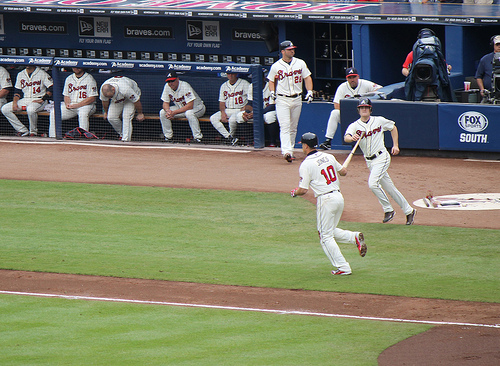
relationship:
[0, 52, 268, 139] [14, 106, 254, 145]
baseball players sitting on bench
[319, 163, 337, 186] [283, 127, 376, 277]
number on player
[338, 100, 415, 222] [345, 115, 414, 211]
baseball player wearing uniform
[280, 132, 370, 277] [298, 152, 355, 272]
baseball player wearing uniform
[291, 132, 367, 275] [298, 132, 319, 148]
baseball player wearing baseball helmet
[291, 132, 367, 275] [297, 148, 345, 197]
baseball player wearing shirt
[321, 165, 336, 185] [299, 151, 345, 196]
number on shirt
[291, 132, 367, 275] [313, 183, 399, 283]
baseball player wearing pants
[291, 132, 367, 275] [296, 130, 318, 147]
baseball player wearing helmet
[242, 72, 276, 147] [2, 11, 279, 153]
baseball players sitting in dugout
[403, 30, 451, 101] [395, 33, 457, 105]
cloth over camera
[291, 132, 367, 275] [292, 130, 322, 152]
baseball player wearing baseball helmet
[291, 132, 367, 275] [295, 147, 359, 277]
baseball player wearing uniform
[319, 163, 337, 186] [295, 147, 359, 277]
number on uniform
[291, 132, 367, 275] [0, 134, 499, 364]
baseball player on field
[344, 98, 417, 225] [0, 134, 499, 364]
baseball player on field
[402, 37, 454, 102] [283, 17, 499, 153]
camera on sideline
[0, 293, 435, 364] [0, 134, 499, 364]
grass on field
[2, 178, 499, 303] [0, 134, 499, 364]
grass on field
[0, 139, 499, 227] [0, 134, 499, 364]
dirt on field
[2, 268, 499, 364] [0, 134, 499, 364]
dirt on field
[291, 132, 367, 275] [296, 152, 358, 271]
baseball player wearing white uniform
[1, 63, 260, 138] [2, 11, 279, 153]
baseball players sitting in dugout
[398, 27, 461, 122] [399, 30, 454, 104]
cameraman behind a camera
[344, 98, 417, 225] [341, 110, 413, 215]
baseball player wearing uniform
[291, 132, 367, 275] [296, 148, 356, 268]
baseball player wearing uniform